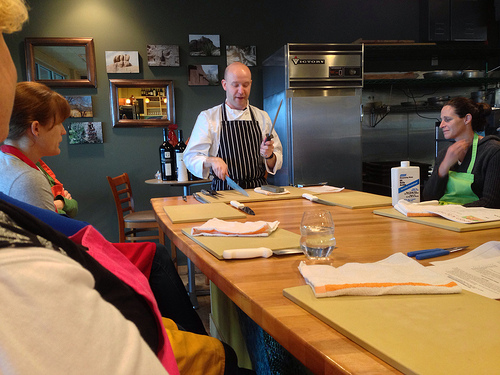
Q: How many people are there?
A: Four.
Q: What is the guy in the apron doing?
A: Demonstrating how to sharpen.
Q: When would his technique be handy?
A: When knives are dull.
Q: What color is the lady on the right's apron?
A: Green.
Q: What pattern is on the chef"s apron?
A: Stripes.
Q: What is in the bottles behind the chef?
A: Wine.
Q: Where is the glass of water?
A: On the counter.